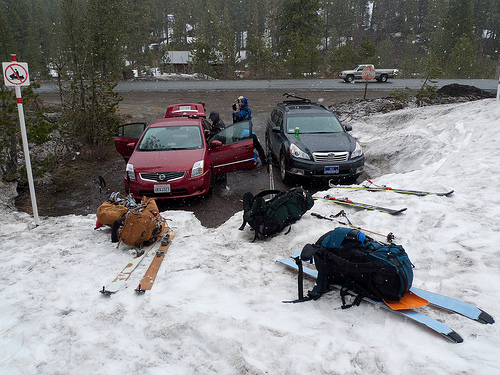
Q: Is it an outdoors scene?
A: Yes, it is outdoors.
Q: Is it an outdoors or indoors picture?
A: It is outdoors.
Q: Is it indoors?
A: No, it is outdoors.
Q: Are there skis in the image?
A: Yes, there are skis.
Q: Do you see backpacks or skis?
A: Yes, there are skis.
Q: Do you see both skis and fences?
A: No, there are skis but no fences.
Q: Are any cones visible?
A: No, there are no cones.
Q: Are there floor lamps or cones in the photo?
A: No, there are no cones or floor lamps.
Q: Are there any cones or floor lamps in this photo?
A: No, there are no cones or floor lamps.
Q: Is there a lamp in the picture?
A: No, there are no lamps.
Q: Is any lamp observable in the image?
A: No, there are no lamps.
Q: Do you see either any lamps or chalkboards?
A: No, there are no lamps or chalkboards.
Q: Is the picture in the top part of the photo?
A: Yes, the picture is in the top of the image.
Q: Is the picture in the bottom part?
A: No, the picture is in the top of the image.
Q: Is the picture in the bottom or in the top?
A: The picture is in the top of the image.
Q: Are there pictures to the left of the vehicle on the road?
A: Yes, there is a picture to the left of the car.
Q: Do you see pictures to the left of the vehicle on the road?
A: Yes, there is a picture to the left of the car.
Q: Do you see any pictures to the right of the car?
A: No, the picture is to the left of the car.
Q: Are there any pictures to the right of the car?
A: No, the picture is to the left of the car.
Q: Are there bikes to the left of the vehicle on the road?
A: No, there is a picture to the left of the car.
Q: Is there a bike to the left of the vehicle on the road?
A: No, there is a picture to the left of the car.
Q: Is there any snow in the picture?
A: Yes, there is snow.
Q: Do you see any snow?
A: Yes, there is snow.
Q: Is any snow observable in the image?
A: Yes, there is snow.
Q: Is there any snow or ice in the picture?
A: Yes, there is snow.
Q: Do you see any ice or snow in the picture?
A: Yes, there is snow.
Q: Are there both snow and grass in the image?
A: No, there is snow but no grass.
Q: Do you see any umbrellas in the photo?
A: No, there are no umbrellas.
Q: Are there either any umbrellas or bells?
A: No, there are no umbrellas or bells.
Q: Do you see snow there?
A: Yes, there is snow.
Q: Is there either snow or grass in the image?
A: Yes, there is snow.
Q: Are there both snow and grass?
A: No, there is snow but no grass.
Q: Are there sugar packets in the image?
A: No, there are no sugar packets.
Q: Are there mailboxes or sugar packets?
A: No, there are no sugar packets or mailboxes.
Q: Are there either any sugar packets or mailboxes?
A: No, there are no sugar packets or mailboxes.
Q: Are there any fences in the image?
A: No, there are no fences.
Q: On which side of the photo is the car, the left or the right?
A: The car is on the right of the image.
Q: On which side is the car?
A: The car is on the right of the image.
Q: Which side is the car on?
A: The car is on the right of the image.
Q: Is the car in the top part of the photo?
A: Yes, the car is in the top of the image.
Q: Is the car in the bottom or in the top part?
A: The car is in the top of the image.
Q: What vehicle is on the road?
A: The vehicle is a car.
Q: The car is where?
A: The car is on the road.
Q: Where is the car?
A: The car is on the road.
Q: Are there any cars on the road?
A: Yes, there is a car on the road.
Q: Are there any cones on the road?
A: No, there is a car on the road.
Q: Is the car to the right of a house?
A: No, the car is to the right of a picture.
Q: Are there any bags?
A: Yes, there is a bag.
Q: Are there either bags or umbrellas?
A: Yes, there is a bag.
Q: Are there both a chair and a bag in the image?
A: No, there is a bag but no chairs.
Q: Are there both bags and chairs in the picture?
A: No, there is a bag but no chairs.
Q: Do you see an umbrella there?
A: No, there are no umbrellas.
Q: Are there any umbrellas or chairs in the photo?
A: No, there are no umbrellas or chairs.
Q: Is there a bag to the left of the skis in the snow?
A: Yes, there is a bag to the left of the skis.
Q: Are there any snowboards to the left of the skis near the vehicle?
A: No, there is a bag to the left of the skis.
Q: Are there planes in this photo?
A: No, there are no planes.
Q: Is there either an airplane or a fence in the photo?
A: No, there are no airplanes or fences.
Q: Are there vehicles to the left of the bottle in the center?
A: Yes, there is a vehicle to the left of the bottle.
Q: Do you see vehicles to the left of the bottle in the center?
A: Yes, there is a vehicle to the left of the bottle.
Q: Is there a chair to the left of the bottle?
A: No, there is a vehicle to the left of the bottle.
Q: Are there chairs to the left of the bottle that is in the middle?
A: No, there is a vehicle to the left of the bottle.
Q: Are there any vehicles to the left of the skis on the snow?
A: Yes, there is a vehicle to the left of the skis.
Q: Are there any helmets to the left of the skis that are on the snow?
A: No, there is a vehicle to the left of the skis.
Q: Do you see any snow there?
A: Yes, there is snow.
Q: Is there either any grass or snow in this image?
A: Yes, there is snow.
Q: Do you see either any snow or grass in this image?
A: Yes, there is snow.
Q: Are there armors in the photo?
A: No, there are no armors.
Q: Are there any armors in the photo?
A: No, there are no armors.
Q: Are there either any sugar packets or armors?
A: No, there are no armors or sugar packets.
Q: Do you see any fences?
A: No, there are no fences.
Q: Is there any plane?
A: No, there are no airplanes.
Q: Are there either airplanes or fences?
A: No, there are no airplanes or fences.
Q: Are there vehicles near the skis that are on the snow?
A: Yes, there is a vehicle near the skis.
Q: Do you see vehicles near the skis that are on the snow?
A: Yes, there is a vehicle near the skis.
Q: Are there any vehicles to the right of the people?
A: Yes, there is a vehicle to the right of the people.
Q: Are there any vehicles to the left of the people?
A: No, the vehicle is to the right of the people.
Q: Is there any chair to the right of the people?
A: No, there is a vehicle to the right of the people.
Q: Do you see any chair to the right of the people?
A: No, there is a vehicle to the right of the people.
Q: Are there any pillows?
A: No, there are no pillows.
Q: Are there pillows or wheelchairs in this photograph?
A: No, there are no pillows or wheelchairs.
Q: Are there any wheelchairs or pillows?
A: No, there are no pillows or wheelchairs.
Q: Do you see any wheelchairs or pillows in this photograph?
A: No, there are no pillows or wheelchairs.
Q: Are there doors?
A: Yes, there is a door.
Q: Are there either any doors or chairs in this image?
A: Yes, there is a door.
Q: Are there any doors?
A: Yes, there is a door.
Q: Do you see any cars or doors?
A: Yes, there is a door.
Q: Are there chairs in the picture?
A: No, there are no chairs.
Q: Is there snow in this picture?
A: Yes, there is snow.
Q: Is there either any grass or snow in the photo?
A: Yes, there is snow.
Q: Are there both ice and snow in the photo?
A: No, there is snow but no ice.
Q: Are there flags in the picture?
A: No, there are no flags.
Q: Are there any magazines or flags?
A: No, there are no flags or magazines.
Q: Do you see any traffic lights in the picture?
A: No, there are no traffic lights.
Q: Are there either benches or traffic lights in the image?
A: No, there are no traffic lights or benches.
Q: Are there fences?
A: No, there are no fences.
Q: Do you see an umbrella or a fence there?
A: No, there are no fences or umbrellas.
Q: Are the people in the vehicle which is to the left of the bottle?
A: Yes, the people are in the vehicle.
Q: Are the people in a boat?
A: No, the people are in the vehicle.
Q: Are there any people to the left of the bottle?
A: Yes, there are people to the left of the bottle.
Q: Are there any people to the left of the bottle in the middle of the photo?
A: Yes, there are people to the left of the bottle.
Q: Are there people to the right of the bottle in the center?
A: No, the people are to the left of the bottle.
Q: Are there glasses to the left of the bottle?
A: No, there are people to the left of the bottle.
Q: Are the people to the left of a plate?
A: No, the people are to the left of the bottle.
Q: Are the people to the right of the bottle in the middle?
A: No, the people are to the left of the bottle.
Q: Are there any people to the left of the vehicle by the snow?
A: Yes, there are people to the left of the vehicle.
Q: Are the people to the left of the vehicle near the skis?
A: Yes, the people are to the left of the vehicle.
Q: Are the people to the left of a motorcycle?
A: No, the people are to the left of the vehicle.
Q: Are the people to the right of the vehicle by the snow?
A: No, the people are to the left of the vehicle.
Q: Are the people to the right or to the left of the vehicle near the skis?
A: The people are to the left of the vehicle.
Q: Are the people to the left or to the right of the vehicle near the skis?
A: The people are to the left of the vehicle.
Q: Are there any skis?
A: Yes, there are skis.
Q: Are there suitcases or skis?
A: Yes, there are skis.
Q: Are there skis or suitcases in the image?
A: Yes, there are skis.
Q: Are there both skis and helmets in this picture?
A: No, there are skis but no helmets.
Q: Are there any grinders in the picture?
A: No, there are no grinders.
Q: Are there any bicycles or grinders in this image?
A: No, there are no grinders or bicycles.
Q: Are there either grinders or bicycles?
A: No, there are no grinders or bicycles.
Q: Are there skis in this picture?
A: Yes, there are skis.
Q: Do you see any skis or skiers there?
A: Yes, there are skis.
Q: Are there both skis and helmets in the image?
A: No, there are skis but no helmets.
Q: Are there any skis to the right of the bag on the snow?
A: Yes, there are skis to the right of the bag.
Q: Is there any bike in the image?
A: No, there are no bikes.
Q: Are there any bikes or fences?
A: No, there are no bikes or fences.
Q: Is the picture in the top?
A: Yes, the picture is in the top of the image.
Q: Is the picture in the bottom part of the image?
A: No, the picture is in the top of the image.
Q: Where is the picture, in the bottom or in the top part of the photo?
A: The picture is in the top of the image.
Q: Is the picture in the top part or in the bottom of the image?
A: The picture is in the top of the image.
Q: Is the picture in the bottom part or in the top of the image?
A: The picture is in the top of the image.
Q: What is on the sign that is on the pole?
A: The picture is on the sign.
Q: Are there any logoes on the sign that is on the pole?
A: No, there is a picture on the sign.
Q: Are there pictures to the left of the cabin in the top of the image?
A: Yes, there is a picture to the left of the cabin.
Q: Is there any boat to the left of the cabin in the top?
A: No, there is a picture to the left of the cabin.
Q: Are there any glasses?
A: No, there are no glasses.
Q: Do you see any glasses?
A: No, there are no glasses.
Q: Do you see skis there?
A: Yes, there are skis.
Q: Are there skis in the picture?
A: Yes, there are skis.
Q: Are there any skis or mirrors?
A: Yes, there are skis.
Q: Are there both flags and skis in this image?
A: No, there are skis but no flags.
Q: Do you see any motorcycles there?
A: No, there are no motorcycles.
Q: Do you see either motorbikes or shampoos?
A: No, there are no motorbikes or shampoos.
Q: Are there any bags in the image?
A: Yes, there is a bag.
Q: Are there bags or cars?
A: Yes, there is a bag.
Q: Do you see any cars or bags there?
A: Yes, there is a bag.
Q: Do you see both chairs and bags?
A: No, there is a bag but no chairs.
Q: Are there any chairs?
A: No, there are no chairs.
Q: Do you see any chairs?
A: No, there are no chairs.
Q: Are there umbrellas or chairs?
A: No, there are no chairs or umbrellas.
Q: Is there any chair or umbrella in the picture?
A: No, there are no chairs or umbrellas.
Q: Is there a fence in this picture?
A: No, there are no fences.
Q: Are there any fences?
A: No, there are no fences.